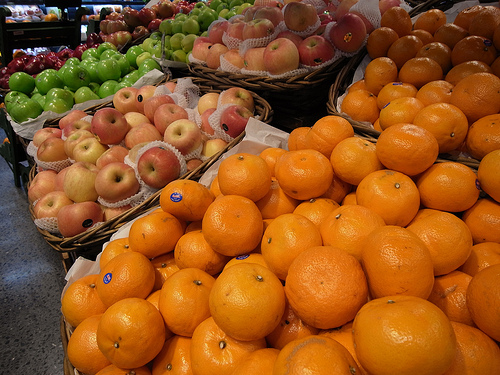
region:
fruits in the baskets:
[42, 70, 407, 350]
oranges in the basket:
[173, 215, 388, 322]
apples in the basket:
[50, 128, 151, 200]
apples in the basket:
[42, 67, 114, 92]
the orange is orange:
[290, 260, 337, 300]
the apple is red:
[97, 168, 133, 185]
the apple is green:
[66, 68, 77, 73]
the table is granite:
[5, 262, 45, 322]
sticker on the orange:
[169, 190, 181, 205]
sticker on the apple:
[73, 218, 94, 230]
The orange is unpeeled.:
[271, 143, 338, 200]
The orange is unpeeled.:
[213, 148, 275, 203]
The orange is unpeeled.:
[156, 175, 218, 223]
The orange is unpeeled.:
[197, 192, 269, 258]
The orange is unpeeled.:
[258, 210, 322, 285]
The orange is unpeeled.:
[276, 237, 372, 332]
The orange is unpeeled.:
[201, 258, 288, 345]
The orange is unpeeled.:
[88, 289, 171, 371]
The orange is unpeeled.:
[344, 287, 461, 374]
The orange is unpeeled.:
[358, 218, 439, 311]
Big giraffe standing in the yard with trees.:
[340, 71, 381, 156]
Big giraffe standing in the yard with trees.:
[176, 98, 183, 173]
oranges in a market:
[223, 157, 470, 372]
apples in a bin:
[63, 84, 186, 192]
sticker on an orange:
[98, 265, 119, 291]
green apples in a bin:
[12, 62, 110, 103]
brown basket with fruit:
[41, 220, 116, 259]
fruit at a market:
[14, 7, 487, 357]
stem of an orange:
[251, 268, 272, 285]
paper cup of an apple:
[150, 134, 184, 155]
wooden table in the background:
[3, 16, 86, 58]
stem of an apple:
[111, 168, 126, 185]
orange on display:
[206, 262, 284, 341]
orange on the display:
[90, 295, 171, 367]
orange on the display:
[90, 250, 155, 300]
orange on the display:
[362, 220, 427, 291]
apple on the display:
[137, 147, 178, 183]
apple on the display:
[92, 106, 128, 141]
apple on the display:
[147, 103, 190, 119]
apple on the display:
[10, 70, 32, 92]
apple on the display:
[12, 95, 40, 116]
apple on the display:
[93, 56, 121, 78]